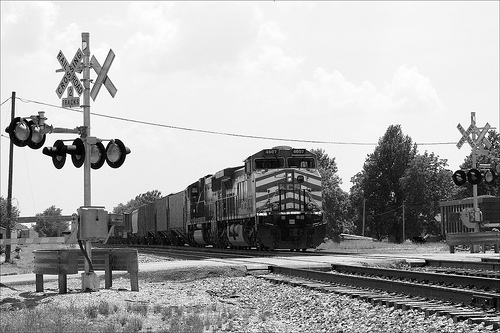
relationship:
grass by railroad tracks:
[0, 301, 218, 333] [104, 236, 498, 325]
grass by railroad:
[0, 301, 218, 333] [107, 236, 499, 328]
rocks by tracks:
[212, 269, 281, 311] [258, 251, 498, 328]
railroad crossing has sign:
[3, 26, 499, 278] [56, 49, 91, 103]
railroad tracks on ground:
[104, 240, 500, 325] [2, 239, 497, 331]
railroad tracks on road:
[104, 240, 500, 325] [1, 244, 498, 304]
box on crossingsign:
[72, 195, 124, 244] [54, 47, 117, 101]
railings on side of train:
[216, 187, 249, 221] [130, 136, 374, 263]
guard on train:
[259, 211, 353, 243] [156, 134, 350, 229]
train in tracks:
[102, 134, 337, 253] [266, 245, 498, 306]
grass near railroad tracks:
[42, 302, 194, 331] [150, 200, 497, 321]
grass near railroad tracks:
[0, 301, 218, 333] [318, 260, 499, 310]